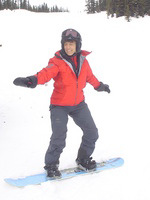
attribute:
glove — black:
[11, 73, 37, 90]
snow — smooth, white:
[0, 117, 145, 199]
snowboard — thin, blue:
[2, 161, 135, 185]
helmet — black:
[60, 28, 81, 56]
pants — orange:
[46, 53, 93, 101]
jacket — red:
[49, 55, 87, 102]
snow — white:
[92, 61, 149, 143]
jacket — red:
[26, 48, 99, 104]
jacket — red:
[35, 58, 92, 101]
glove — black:
[93, 81, 110, 93]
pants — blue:
[43, 100, 98, 169]